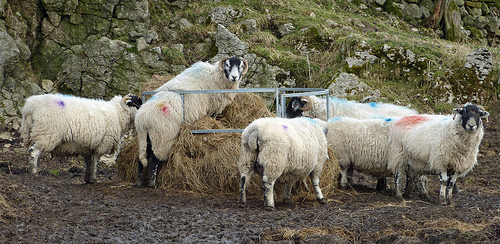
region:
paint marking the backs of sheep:
[360, 92, 435, 144]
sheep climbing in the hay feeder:
[119, 49, 260, 171]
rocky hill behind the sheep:
[14, 2, 229, 98]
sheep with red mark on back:
[390, 103, 487, 195]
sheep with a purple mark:
[21, 83, 143, 183]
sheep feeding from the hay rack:
[134, 52, 346, 207]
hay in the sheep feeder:
[159, 84, 277, 190]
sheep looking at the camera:
[133, 46, 248, 182]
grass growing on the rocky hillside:
[253, 5, 435, 86]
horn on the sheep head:
[295, 92, 314, 115]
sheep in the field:
[12, 82, 131, 186]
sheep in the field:
[231, 110, 329, 213]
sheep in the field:
[132, 44, 255, 179]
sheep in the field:
[391, 105, 479, 197]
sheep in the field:
[317, 107, 388, 178]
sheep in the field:
[288, 88, 410, 114]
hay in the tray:
[183, 132, 234, 196]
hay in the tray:
[231, 85, 277, 130]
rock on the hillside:
[197, 19, 257, 50]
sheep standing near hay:
[20, 62, 481, 213]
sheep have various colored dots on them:
[10, 57, 496, 210]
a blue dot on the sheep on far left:
[51, 95, 71, 110]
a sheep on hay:
[132, 46, 303, 186]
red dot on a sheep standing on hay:
[155, 98, 170, 113]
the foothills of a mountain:
[0, 3, 492, 224]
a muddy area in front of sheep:
[0, 191, 497, 237]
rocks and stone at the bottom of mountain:
[15, 0, 486, 95]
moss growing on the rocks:
[370, 40, 431, 80]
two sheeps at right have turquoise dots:
[326, 82, 403, 189]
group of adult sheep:
[23, 44, 488, 216]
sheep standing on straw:
[135, 52, 250, 187]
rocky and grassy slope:
[8, 3, 497, 90]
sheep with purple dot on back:
[16, 83, 131, 181]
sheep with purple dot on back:
[241, 112, 325, 196]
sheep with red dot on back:
[131, 55, 243, 190]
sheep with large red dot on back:
[388, 107, 489, 204]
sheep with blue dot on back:
[289, 94, 417, 113]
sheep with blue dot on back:
[324, 114, 393, 189]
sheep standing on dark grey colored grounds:
[16, 54, 486, 226]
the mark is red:
[147, 96, 181, 124]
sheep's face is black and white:
[212, 47, 257, 98]